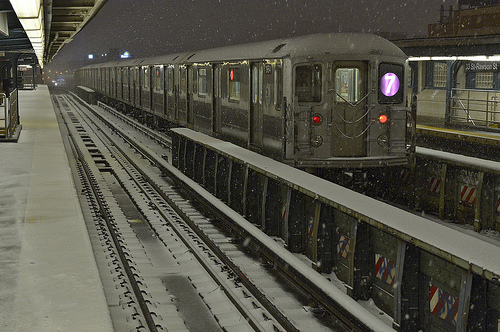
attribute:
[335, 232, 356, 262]
sign — striped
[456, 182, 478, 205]
sign — striped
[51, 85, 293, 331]
track — empty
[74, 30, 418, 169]
train — large, silver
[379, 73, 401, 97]
circle — purple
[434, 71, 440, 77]
block — glass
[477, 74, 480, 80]
block — glass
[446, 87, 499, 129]
railing — metal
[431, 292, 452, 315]
line — red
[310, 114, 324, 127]
light — red, small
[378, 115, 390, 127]
light — small, red